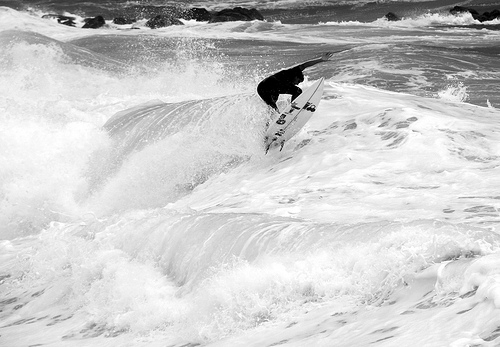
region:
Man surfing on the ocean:
[249, 47, 328, 142]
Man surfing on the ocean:
[253, 51, 334, 149]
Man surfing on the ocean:
[228, 35, 343, 153]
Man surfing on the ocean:
[253, 50, 329, 147]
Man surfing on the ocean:
[238, 39, 341, 161]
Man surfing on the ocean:
[243, 35, 334, 149]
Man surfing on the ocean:
[226, 39, 333, 144]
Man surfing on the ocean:
[243, 43, 361, 151]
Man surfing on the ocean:
[243, 47, 330, 141]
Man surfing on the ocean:
[218, 43, 354, 169]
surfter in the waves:
[231, 36, 348, 167]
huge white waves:
[48, 80, 235, 305]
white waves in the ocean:
[322, 127, 474, 334]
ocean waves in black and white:
[35, 119, 170, 329]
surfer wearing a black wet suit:
[233, 34, 312, 104]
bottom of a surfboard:
[259, 73, 328, 156]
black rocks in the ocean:
[70, 4, 276, 53]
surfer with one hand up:
[248, 44, 353, 135]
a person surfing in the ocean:
[251, 40, 343, 145]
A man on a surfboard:
[254, 53, 337, 111]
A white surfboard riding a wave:
[255, 76, 327, 154]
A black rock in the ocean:
[80, 15, 108, 30]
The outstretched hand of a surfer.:
[319, 49, 336, 62]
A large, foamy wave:
[8, 206, 494, 345]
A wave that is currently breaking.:
[40, 80, 341, 217]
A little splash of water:
[435, 81, 469, 103]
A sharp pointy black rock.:
[384, 11, 401, 22]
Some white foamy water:
[239, 305, 467, 345]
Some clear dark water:
[233, 43, 280, 55]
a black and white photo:
[5, 2, 498, 337]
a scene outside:
[6, 4, 497, 343]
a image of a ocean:
[6, 7, 498, 345]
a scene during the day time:
[3, 5, 498, 338]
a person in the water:
[235, 35, 351, 184]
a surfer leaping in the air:
[242, 47, 352, 166]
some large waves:
[5, 78, 487, 345]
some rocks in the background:
[35, 0, 258, 42]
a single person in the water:
[245, 23, 380, 243]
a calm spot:
[72, 23, 362, 110]